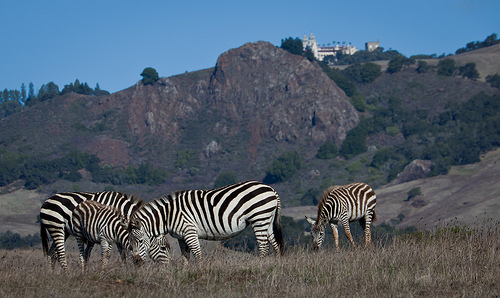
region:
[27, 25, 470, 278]
zebras standing below castle and boulders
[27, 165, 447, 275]
adult and young zebras eating grass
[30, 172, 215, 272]
young zebra surrounded by adults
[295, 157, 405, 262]
zebra eating alone with bent neck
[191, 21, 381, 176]
gray and red round boulder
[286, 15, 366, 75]
white building with towers on mountain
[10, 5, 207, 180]
clear blue sky behind trees and slopes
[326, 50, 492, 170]
bushes growing around sloped dirt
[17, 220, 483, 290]
green and gray grass under zebras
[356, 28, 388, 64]
boxy building hidden by bushes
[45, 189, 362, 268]
five zebras eating grass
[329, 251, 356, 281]
the grass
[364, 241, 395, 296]
the grass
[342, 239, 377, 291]
the grass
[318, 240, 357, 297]
the grass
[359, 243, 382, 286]
the grass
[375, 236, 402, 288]
the grass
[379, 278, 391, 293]
the grass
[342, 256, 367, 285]
the grass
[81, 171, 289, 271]
the zebra is eating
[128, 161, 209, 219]
the zebra is eating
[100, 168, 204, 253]
the zebra is eating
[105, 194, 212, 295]
the zebra is eating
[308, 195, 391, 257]
black and white zebra eating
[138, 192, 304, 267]
black and white zebra eating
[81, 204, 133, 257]
black and white zebra eating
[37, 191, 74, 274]
black and white zebra eating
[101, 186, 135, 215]
black and white zebra eating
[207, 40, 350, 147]
stone mountain in background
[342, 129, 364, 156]
small green bush on hill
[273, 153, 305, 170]
small green bush on hill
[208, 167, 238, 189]
small green bush on hill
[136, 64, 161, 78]
small green bush on hill